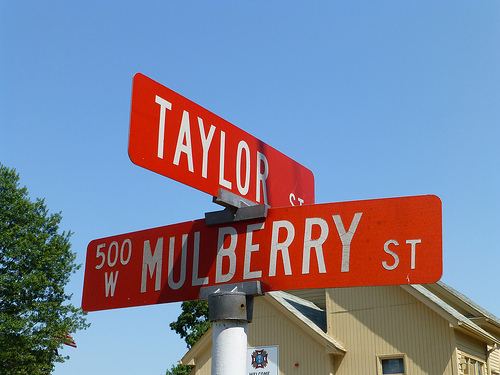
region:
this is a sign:
[115, 66, 337, 223]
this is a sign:
[80, 191, 441, 331]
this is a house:
[170, 245, 495, 371]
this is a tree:
[0, 166, 95, 371]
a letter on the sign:
[325, 199, 368, 279]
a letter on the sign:
[260, 220, 310, 285]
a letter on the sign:
[153, 88, 176, 161]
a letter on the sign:
[194, 111, 220, 186]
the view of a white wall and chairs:
[291, 333, 316, 350]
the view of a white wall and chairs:
[301, 300, 309, 320]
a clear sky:
[383, 75, 465, 147]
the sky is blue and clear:
[294, 68, 381, 127]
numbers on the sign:
[88, 238, 136, 268]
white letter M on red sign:
[136, 235, 168, 297]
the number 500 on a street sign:
[94, 237, 131, 268]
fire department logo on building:
[251, 350, 273, 371]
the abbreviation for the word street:
[375, 235, 426, 277]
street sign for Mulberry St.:
[136, 206, 427, 288]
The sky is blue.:
[40, 8, 468, 124]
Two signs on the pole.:
[64, 120, 424, 367]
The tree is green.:
[11, 205, 62, 346]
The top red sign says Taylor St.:
[140, 97, 310, 204]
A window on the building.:
[373, 343, 418, 373]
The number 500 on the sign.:
[91, 242, 136, 265]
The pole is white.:
[207, 318, 249, 374]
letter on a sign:
[335, 210, 370, 276]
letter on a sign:
[293, 218, 333, 273]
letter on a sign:
[266, 215, 287, 276]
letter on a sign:
[235, 221, 270, 279]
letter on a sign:
[210, 225, 236, 285]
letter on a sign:
[188, 227, 209, 292]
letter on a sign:
[161, 227, 184, 289]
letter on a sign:
[130, 230, 165, 307]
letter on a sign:
[361, 235, 403, 276]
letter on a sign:
[402, 232, 428, 279]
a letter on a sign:
[135, 229, 162, 299]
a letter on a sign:
[168, 228, 188, 295]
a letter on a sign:
[173, 213, 210, 295]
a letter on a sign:
[210, 222, 238, 285]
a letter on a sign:
[240, 222, 262, 285]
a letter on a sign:
[261, 216, 289, 276]